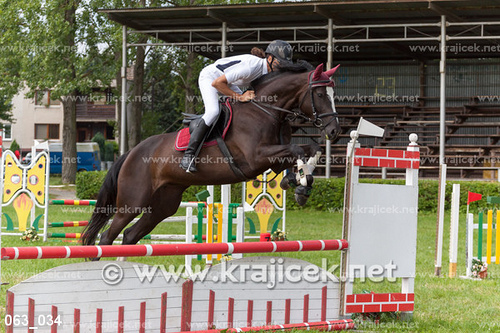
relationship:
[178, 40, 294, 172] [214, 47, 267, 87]
rider wearing shirt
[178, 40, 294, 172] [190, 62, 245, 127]
rider wearing pants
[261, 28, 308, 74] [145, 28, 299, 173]
helmet on jockey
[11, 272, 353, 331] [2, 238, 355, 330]
vertical lines on panels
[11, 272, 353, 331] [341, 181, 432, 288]
vertical lines on white panel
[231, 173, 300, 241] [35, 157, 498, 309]
butterfly support ends poles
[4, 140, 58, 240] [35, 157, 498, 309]
butterfly support ends poles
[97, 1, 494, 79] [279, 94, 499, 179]
roof over stands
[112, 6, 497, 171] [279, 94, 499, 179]
metal supports over stands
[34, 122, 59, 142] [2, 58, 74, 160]
window on building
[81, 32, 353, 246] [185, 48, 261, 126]
rider wears outfit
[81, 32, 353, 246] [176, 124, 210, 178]
rider wears boot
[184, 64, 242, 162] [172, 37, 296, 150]
leg under woman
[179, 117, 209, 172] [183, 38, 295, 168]
boot on rider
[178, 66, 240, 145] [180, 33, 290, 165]
pants on rider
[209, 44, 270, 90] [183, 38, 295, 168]
shirt on rider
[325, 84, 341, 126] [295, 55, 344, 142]
mark on horse's head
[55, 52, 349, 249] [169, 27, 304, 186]
horse on rider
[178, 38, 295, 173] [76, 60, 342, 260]
jokey on horse